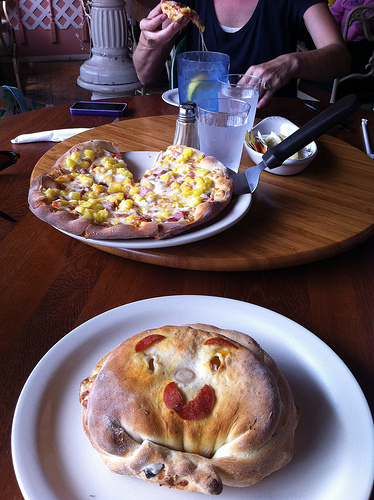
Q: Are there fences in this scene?
A: No, there are no fences.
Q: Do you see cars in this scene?
A: No, there are no cars.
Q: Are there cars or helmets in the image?
A: No, there are no cars or helmets.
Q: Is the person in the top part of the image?
A: Yes, the person is in the top of the image.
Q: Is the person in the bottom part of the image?
A: No, the person is in the top of the image.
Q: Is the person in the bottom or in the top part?
A: The person is in the top of the image.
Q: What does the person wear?
A: The person wears a shirt.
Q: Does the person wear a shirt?
A: Yes, the person wears a shirt.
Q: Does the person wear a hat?
A: No, the person wears a shirt.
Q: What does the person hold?
A: The person holds the pizza.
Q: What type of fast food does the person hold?
A: The person holds the pizza.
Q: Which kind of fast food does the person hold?
A: The person holds the pizza.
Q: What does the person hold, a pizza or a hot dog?
A: The person holds a pizza.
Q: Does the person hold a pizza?
A: Yes, the person holds a pizza.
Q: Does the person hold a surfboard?
A: No, the person holds a pizza.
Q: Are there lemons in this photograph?
A: Yes, there is a lemon.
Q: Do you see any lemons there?
A: Yes, there is a lemon.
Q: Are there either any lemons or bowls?
A: Yes, there is a lemon.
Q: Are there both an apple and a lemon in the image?
A: No, there is a lemon but no apples.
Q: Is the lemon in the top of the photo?
A: Yes, the lemon is in the top of the image.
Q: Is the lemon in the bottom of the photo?
A: No, the lemon is in the top of the image.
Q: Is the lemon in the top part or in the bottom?
A: The lemon is in the top of the image.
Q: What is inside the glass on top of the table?
A: The lemon is inside the glass.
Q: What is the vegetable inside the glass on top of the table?
A: The vegetable is a lemon.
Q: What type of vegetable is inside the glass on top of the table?
A: The vegetable is a lemon.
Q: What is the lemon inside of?
A: The lemon is inside the glass.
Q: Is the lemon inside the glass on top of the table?
A: Yes, the lemon is inside the glass.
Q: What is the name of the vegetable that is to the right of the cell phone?
A: The vegetable is a lemon.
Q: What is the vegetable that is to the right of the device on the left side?
A: The vegetable is a lemon.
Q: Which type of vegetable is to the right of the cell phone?
A: The vegetable is a lemon.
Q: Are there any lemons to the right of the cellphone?
A: Yes, there is a lemon to the right of the cellphone.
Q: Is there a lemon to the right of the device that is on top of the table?
A: Yes, there is a lemon to the right of the cellphone.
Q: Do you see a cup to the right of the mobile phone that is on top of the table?
A: No, there is a lemon to the right of the mobile phone.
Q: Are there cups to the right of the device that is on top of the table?
A: No, there is a lemon to the right of the mobile phone.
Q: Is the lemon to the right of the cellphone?
A: Yes, the lemon is to the right of the cellphone.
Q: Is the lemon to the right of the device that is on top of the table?
A: Yes, the lemon is to the right of the cellphone.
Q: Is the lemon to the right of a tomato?
A: No, the lemon is to the right of the cellphone.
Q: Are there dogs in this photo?
A: No, there are no dogs.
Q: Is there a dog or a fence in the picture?
A: No, there are no dogs or fences.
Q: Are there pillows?
A: No, there are no pillows.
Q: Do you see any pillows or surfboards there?
A: No, there are no pillows or surfboards.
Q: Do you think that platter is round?
A: Yes, the platter is round.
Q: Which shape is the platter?
A: The platter is round.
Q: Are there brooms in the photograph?
A: No, there are no brooms.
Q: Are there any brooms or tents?
A: No, there are no brooms or tents.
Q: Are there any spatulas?
A: Yes, there is a spatula.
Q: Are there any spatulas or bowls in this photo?
A: Yes, there is a spatula.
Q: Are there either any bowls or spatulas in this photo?
A: Yes, there is a spatula.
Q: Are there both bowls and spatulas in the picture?
A: Yes, there are both a spatula and a bowl.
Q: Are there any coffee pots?
A: No, there are no coffee pots.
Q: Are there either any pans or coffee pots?
A: No, there are no coffee pots or pans.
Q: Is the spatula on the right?
A: Yes, the spatula is on the right of the image.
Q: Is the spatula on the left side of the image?
A: No, the spatula is on the right of the image.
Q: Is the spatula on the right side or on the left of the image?
A: The spatula is on the right of the image.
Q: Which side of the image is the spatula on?
A: The spatula is on the right of the image.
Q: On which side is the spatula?
A: The spatula is on the right of the image.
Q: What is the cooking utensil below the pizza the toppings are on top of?
A: The cooking utensil is a spatula.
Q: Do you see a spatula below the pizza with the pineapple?
A: Yes, there is a spatula below the pizza.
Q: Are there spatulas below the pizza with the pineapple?
A: Yes, there is a spatula below the pizza.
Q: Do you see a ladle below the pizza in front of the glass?
A: No, there is a spatula below the pizza.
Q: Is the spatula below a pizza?
A: Yes, the spatula is below a pizza.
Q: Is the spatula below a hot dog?
A: No, the spatula is below a pizza.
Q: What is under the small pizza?
A: The spatula is under the pizza.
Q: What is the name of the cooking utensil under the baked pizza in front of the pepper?
A: The cooking utensil is a spatula.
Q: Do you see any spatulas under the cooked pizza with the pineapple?
A: Yes, there is a spatula under the pizza.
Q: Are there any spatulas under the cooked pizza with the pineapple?
A: Yes, there is a spatula under the pizza.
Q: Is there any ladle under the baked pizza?
A: No, there is a spatula under the pizza.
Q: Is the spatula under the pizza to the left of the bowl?
A: Yes, the spatula is under the pizza.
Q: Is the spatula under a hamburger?
A: No, the spatula is under the pizza.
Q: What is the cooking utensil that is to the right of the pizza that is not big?
A: The cooking utensil is a spatula.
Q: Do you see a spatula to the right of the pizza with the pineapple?
A: Yes, there is a spatula to the right of the pizza.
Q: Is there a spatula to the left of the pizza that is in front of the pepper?
A: No, the spatula is to the right of the pizza.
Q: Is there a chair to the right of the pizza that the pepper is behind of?
A: No, there is a spatula to the right of the pizza.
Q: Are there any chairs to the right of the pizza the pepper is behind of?
A: No, there is a spatula to the right of the pizza.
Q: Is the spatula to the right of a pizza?
A: Yes, the spatula is to the right of a pizza.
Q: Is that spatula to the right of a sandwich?
A: No, the spatula is to the right of a pizza.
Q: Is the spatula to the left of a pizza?
A: No, the spatula is to the right of a pizza.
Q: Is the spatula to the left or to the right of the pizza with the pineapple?
A: The spatula is to the right of the pizza.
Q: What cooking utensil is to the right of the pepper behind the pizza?
A: The cooking utensil is a spatula.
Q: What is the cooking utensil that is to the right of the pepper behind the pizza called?
A: The cooking utensil is a spatula.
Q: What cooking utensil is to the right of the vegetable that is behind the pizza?
A: The cooking utensil is a spatula.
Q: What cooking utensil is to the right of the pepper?
A: The cooking utensil is a spatula.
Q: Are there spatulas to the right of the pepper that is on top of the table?
A: Yes, there is a spatula to the right of the pepper.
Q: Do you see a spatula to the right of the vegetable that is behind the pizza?
A: Yes, there is a spatula to the right of the pepper.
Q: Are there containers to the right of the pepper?
A: No, there is a spatula to the right of the pepper.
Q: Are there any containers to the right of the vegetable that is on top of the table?
A: No, there is a spatula to the right of the pepper.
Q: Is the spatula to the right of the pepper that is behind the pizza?
A: Yes, the spatula is to the right of the pepper.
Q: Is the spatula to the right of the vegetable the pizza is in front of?
A: Yes, the spatula is to the right of the pepper.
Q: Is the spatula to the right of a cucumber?
A: No, the spatula is to the right of the pepper.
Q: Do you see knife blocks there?
A: No, there are no knife blocks.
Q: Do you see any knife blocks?
A: No, there are no knife blocks.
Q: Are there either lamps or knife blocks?
A: No, there are no knife blocks or lamps.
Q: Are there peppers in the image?
A: Yes, there is a pepper.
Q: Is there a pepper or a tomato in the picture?
A: Yes, there is a pepper.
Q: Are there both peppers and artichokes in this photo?
A: No, there is a pepper but no artichokes.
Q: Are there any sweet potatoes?
A: No, there are no sweet potatoes.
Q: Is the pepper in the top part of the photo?
A: Yes, the pepper is in the top of the image.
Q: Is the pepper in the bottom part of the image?
A: No, the pepper is in the top of the image.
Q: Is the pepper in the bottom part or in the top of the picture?
A: The pepper is in the top of the image.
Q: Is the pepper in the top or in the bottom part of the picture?
A: The pepper is in the top of the image.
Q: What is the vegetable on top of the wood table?
A: The vegetable is a pepper.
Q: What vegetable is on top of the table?
A: The vegetable is a pepper.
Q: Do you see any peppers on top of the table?
A: Yes, there is a pepper on top of the table.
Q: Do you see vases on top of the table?
A: No, there is a pepper on top of the table.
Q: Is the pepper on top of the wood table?
A: Yes, the pepper is on top of the table.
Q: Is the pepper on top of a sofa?
A: No, the pepper is on top of the table.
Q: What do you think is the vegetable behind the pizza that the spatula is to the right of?
A: The vegetable is a pepper.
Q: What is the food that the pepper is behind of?
A: The food is a pizza.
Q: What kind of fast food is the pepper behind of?
A: The pepper is behind the pizza.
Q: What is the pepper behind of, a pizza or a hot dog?
A: The pepper is behind a pizza.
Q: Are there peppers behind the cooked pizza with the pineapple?
A: Yes, there is a pepper behind the pizza.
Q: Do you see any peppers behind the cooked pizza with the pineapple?
A: Yes, there is a pepper behind the pizza.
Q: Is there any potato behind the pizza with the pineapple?
A: No, there is a pepper behind the pizza.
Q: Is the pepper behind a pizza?
A: Yes, the pepper is behind a pizza.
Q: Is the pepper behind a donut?
A: No, the pepper is behind a pizza.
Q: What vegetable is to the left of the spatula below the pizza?
A: The vegetable is a pepper.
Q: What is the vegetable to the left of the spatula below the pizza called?
A: The vegetable is a pepper.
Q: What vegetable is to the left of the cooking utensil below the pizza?
A: The vegetable is a pepper.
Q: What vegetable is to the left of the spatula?
A: The vegetable is a pepper.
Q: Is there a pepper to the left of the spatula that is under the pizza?
A: Yes, there is a pepper to the left of the spatula.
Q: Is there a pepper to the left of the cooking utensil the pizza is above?
A: Yes, there is a pepper to the left of the spatula.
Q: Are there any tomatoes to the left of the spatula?
A: No, there is a pepper to the left of the spatula.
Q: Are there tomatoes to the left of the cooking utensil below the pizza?
A: No, there is a pepper to the left of the spatula.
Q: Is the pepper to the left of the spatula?
A: Yes, the pepper is to the left of the spatula.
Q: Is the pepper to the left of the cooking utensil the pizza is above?
A: Yes, the pepper is to the left of the spatula.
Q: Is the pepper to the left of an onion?
A: No, the pepper is to the left of the spatula.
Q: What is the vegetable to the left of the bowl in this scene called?
A: The vegetable is a pepper.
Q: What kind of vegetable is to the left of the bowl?
A: The vegetable is a pepper.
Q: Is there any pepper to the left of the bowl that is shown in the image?
A: Yes, there is a pepper to the left of the bowl.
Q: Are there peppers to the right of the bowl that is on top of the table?
A: No, the pepper is to the left of the bowl.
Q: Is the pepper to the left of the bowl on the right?
A: Yes, the pepper is to the left of the bowl.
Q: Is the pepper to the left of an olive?
A: No, the pepper is to the left of the bowl.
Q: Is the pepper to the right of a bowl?
A: No, the pepper is to the left of a bowl.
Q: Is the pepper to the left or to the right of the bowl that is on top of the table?
A: The pepper is to the left of the bowl.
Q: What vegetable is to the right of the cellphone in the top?
A: The vegetable is a pepper.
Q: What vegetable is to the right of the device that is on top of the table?
A: The vegetable is a pepper.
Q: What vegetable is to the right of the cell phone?
A: The vegetable is a pepper.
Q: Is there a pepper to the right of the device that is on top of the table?
A: Yes, there is a pepper to the right of the mobile phone.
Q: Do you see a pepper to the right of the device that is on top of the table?
A: Yes, there is a pepper to the right of the mobile phone.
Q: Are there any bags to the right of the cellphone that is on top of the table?
A: No, there is a pepper to the right of the mobile phone.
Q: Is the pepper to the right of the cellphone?
A: Yes, the pepper is to the right of the cellphone.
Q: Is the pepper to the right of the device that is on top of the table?
A: Yes, the pepper is to the right of the cellphone.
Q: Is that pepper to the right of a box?
A: No, the pepper is to the right of the cellphone.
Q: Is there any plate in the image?
A: Yes, there is a plate.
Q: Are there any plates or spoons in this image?
A: Yes, there is a plate.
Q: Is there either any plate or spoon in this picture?
A: Yes, there is a plate.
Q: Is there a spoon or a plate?
A: Yes, there is a plate.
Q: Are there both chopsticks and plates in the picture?
A: No, there is a plate but no chopsticks.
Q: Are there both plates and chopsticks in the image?
A: No, there is a plate but no chopsticks.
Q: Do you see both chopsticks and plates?
A: No, there is a plate but no chopsticks.